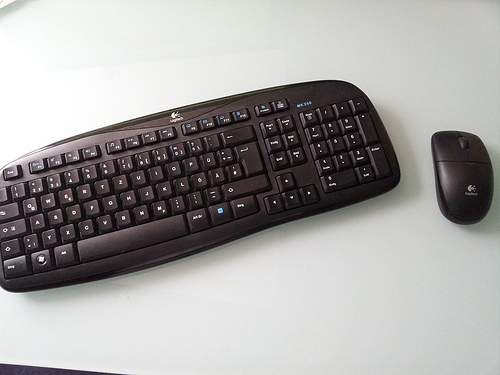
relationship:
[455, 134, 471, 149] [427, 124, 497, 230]
wheel on mouse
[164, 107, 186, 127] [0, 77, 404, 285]
logo on keyboard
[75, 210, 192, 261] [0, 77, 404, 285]
spacebar on keyboard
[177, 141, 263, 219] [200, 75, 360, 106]
keys on board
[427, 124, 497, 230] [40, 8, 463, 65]
mouse on table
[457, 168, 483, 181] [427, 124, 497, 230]
black on mouse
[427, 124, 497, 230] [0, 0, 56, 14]
mouse for computer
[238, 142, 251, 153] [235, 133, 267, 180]
enter on button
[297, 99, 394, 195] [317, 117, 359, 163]
pad of numbers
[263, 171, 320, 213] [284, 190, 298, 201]
keys have arrow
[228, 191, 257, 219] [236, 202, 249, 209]
button for control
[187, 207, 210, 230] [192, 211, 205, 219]
button for alt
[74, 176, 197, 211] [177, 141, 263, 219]
letters on keys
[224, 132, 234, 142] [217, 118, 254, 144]
backspace on button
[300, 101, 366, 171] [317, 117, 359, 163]
keys have numbers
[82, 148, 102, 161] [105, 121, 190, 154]
functions on keys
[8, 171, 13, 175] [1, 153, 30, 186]
escape on key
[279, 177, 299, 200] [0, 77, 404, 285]
arrows on keyboard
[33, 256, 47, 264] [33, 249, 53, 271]
windows shortcut key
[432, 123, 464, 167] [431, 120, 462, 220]
button on left